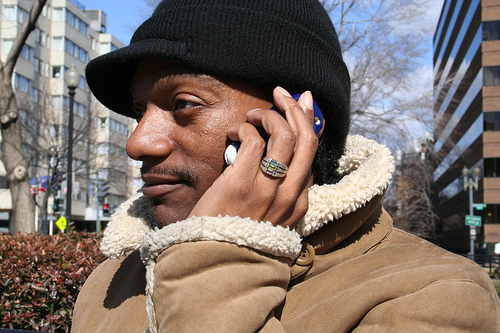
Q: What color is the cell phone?
A: Blue.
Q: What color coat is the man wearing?
A: Tan.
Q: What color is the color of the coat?
A: White.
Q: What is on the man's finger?
A: Ring.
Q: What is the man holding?
A: Cell phone.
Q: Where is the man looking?
A: To the left.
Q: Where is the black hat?
A: On the man's head.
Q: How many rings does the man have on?
A: 1.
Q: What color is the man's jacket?
A: Brown.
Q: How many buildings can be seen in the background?
A: 2.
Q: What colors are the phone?
A: Blue and white.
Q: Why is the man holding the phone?
A: Talking.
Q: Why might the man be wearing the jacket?
A: Because of the cold.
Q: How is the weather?
A: Sunny.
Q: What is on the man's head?
A: The marvin.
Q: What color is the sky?
A: Blue.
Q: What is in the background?
A: Building.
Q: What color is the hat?
A: Black.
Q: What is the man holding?
A: Phone.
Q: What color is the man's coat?
A: Light brown.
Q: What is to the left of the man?
A: Large building.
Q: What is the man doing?
A: Talking.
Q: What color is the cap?
A: Black.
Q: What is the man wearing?
A: Brown coat.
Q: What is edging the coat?
A: Sheep wool.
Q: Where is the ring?
A: On a man's hand.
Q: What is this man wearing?
A: A brown coat.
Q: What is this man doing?
A: Talking on the phone.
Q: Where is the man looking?
A: To his right.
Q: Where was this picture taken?
A: In the city.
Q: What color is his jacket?
A: Brown.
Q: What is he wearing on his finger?
A: A ring.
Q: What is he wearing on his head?
A: A ski cap.